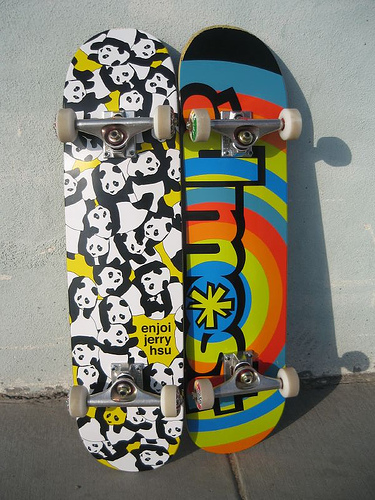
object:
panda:
[98, 295, 137, 334]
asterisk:
[186, 281, 236, 330]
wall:
[0, 0, 374, 401]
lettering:
[177, 82, 265, 416]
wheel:
[278, 107, 302, 140]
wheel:
[55, 108, 77, 141]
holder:
[210, 110, 285, 158]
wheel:
[186, 107, 210, 143]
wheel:
[161, 384, 179, 416]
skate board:
[177, 26, 302, 455]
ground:
[0, 371, 375, 500]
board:
[55, 25, 186, 473]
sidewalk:
[0, 380, 373, 500]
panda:
[107, 444, 170, 473]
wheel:
[153, 104, 172, 140]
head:
[99, 162, 128, 195]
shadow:
[265, 47, 369, 441]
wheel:
[69, 385, 88, 418]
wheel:
[193, 379, 214, 411]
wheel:
[277, 364, 300, 398]